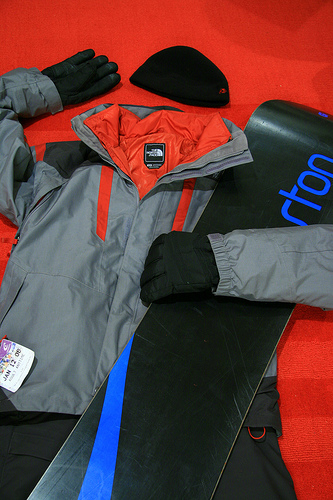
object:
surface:
[0, 0, 333, 499]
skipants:
[81, 296, 302, 495]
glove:
[140, 229, 221, 307]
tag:
[144, 143, 166, 170]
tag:
[247, 417, 266, 440]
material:
[1, 0, 333, 499]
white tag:
[0, 338, 35, 393]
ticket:
[0, 338, 35, 394]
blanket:
[278, 307, 332, 499]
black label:
[144, 142, 166, 169]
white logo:
[147, 149, 163, 157]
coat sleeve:
[207, 228, 333, 314]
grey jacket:
[0, 66, 333, 430]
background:
[0, 0, 333, 498]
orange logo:
[219, 89, 227, 94]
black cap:
[129, 45, 230, 109]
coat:
[1, 66, 333, 439]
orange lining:
[96, 165, 114, 242]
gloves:
[40, 47, 123, 111]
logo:
[279, 154, 332, 226]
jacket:
[0, 67, 333, 430]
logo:
[143, 142, 165, 169]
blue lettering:
[278, 153, 332, 227]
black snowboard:
[24, 99, 332, 499]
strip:
[74, 336, 135, 499]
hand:
[139, 229, 220, 307]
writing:
[3, 347, 29, 389]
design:
[79, 331, 136, 499]